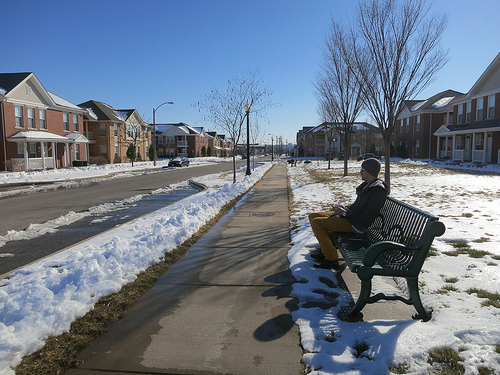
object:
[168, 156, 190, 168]
car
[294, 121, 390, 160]
house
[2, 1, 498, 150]
sky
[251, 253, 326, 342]
black shadow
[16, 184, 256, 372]
grass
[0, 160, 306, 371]
sidewalk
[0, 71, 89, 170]
brick house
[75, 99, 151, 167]
brick house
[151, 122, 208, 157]
brick house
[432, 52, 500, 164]
brick house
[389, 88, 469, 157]
brick house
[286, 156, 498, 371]
snow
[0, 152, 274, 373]
snow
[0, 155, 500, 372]
ground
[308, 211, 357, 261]
pants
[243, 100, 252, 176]
lamp post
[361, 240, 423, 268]
armrest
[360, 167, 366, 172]
sunglasses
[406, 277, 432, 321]
leg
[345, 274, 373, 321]
leg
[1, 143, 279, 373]
grass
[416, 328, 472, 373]
grass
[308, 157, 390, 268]
man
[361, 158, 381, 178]
hat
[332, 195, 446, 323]
bench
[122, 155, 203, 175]
curb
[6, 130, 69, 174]
porch